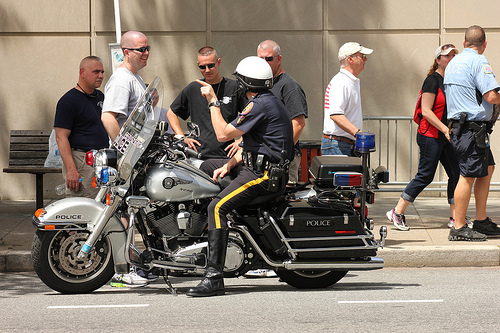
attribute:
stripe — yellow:
[208, 173, 280, 231]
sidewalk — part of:
[2, 185, 499, 272]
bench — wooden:
[3, 128, 63, 209]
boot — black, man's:
[186, 265, 223, 295]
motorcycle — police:
[37, 68, 399, 290]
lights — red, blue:
[83, 149, 121, 189]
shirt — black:
[53, 87, 109, 151]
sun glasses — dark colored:
[121, 44, 153, 57]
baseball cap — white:
[335, 38, 373, 63]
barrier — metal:
[355, 110, 457, 217]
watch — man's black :
[208, 98, 222, 109]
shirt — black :
[171, 77, 246, 162]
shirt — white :
[321, 66, 366, 143]